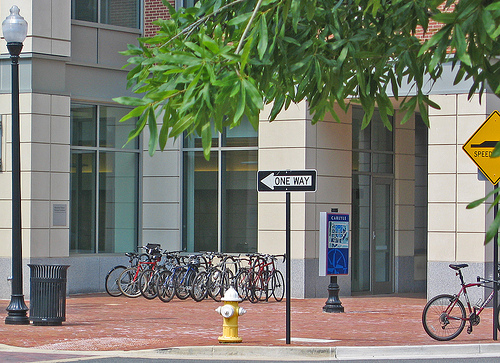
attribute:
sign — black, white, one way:
[257, 170, 317, 192]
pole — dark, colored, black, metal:
[285, 193, 292, 347]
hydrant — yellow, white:
[215, 286, 248, 342]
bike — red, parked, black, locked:
[420, 263, 499, 340]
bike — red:
[121, 254, 157, 298]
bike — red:
[246, 256, 281, 304]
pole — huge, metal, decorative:
[4, 43, 31, 327]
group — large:
[107, 242, 287, 300]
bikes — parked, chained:
[105, 242, 284, 301]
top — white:
[220, 286, 243, 303]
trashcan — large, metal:
[28, 263, 68, 326]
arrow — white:
[262, 171, 314, 189]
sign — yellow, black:
[460, 110, 499, 185]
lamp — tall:
[2, 4, 31, 324]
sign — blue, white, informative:
[319, 210, 348, 277]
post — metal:
[489, 185, 499, 340]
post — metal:
[323, 276, 342, 314]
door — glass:
[371, 181, 391, 292]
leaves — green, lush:
[111, 2, 499, 160]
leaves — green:
[465, 141, 499, 245]